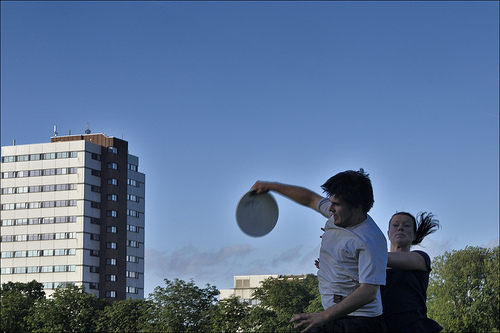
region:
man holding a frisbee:
[230, 173, 278, 240]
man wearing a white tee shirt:
[308, 195, 379, 310]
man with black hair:
[323, 163, 374, 205]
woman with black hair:
[395, 205, 437, 244]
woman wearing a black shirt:
[380, 244, 436, 331]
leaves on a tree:
[423, 238, 495, 307]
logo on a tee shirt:
[327, 288, 343, 308]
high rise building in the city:
[7, 131, 149, 288]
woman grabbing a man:
[305, 215, 450, 306]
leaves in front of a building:
[56, 288, 107, 320]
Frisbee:
[221, 178, 279, 238]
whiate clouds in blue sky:
[25, 6, 109, 64]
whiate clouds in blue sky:
[32, 23, 123, 113]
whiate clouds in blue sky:
[98, 35, 146, 72]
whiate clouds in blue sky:
[165, 73, 193, 100]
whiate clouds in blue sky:
[264, 5, 342, 70]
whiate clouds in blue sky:
[358, 71, 438, 122]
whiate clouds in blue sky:
[401, 98, 466, 152]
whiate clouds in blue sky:
[152, 181, 196, 219]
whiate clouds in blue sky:
[164, 71, 232, 128]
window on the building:
[58, 168, 67, 174]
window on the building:
[56, 188, 71, 198]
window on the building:
[55, 213, 68, 223]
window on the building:
[56, 232, 66, 237]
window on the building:
[54, 246, 66, 253]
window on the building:
[41, 267, 53, 275]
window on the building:
[27, 266, 37, 272]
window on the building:
[64, 266, 76, 274]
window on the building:
[32, 168, 47, 177]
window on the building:
[107, 194, 122, 204]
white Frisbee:
[220, 171, 277, 242]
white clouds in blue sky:
[247, 53, 297, 101]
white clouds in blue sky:
[160, 71, 214, 129]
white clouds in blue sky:
[265, 29, 326, 87]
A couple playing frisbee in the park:
[233, 164, 457, 331]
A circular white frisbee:
[231, 189, 286, 242]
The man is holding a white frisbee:
[225, 168, 333, 258]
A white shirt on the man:
[312, 197, 389, 317]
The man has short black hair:
[320, 169, 380, 211]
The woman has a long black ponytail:
[412, 211, 440, 246]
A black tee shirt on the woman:
[381, 252, 433, 329]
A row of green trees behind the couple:
[14, 267, 495, 332]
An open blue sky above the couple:
[120, 0, 480, 142]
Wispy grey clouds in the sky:
[151, 232, 319, 286]